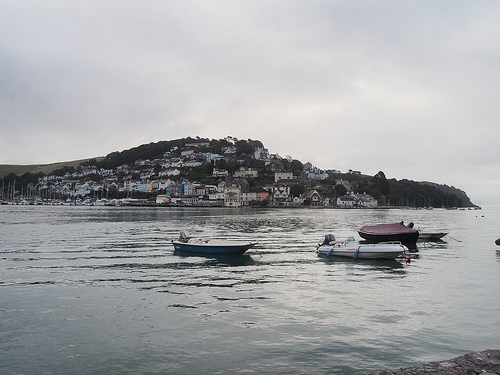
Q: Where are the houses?
A: Background.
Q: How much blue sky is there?
A: None.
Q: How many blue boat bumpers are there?
A: 2.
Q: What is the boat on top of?
A: Water.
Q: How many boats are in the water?
A: 4.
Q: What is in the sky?
A: Clouds.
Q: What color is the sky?
A: White.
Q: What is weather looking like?
A: Overcasted.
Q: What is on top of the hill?
A: Houses.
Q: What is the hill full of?
A: Houses.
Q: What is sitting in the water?
A: Boat.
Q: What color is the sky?
A: Gray.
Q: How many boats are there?
A: Three.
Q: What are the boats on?
A: The water.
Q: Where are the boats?
A: On the water.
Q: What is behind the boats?
A: A hill.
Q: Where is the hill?
A: Behind the boats.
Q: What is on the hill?
A: Houses.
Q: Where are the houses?
A: On the hill.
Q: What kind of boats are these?
A: Motorboats.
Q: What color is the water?
A: Dark gray.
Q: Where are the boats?
A: In the water.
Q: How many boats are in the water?
A: 4.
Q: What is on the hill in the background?
A: Buildings.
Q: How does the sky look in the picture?
A: Cloudy.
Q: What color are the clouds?
A: Gray.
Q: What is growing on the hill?
A: Trees.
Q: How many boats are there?
A: Three.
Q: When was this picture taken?
A: During the day.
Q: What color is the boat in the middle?
A: White.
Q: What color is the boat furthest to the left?
A: Blue and white.